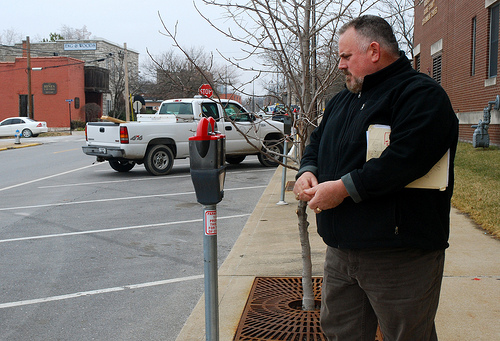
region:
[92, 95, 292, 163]
White pickup truck in parking spot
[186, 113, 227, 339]
Parking meter near street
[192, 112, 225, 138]
Red top of parking meter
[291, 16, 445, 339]
Man in black coat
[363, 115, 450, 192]
Manilla folder under man's arm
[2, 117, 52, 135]
White sedan near brick red building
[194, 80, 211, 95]
Stop sign on street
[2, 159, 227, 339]
White painted lines for parking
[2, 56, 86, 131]
Brick red colored building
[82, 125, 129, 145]
Tailgate of white truck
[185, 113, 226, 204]
a red and black parking meter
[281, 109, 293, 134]
a red and black parking meter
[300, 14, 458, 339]
a man standing on sidewalk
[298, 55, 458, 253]
a black winter coat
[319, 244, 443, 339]
a grey pair of pants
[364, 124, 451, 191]
a manilla file folder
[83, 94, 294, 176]
a parked white pick up truck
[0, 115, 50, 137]
a parked white car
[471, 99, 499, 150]
a grey gas meter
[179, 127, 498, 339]
a paved city sidewalk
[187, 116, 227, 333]
a parking meter on the sidewalk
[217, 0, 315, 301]
a tree with no leaves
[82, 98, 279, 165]
a white pickup truck parked on the street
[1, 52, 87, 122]
a red brick building on the corner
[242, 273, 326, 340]
a metal grate with opening for tree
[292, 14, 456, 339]
a man preparing to put money in parking meter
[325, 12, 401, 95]
a man with a beard and mustache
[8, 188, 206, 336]
white lined parking spaces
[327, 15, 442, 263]
a man holding a folder of papers under arm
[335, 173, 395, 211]
a man wearing black jacket with gray cuffs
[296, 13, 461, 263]
man wearing balck jacket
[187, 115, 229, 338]
silver and red parking meter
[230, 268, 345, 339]
brown grate around tree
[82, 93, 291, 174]
a parked white truck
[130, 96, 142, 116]
back of a stop sign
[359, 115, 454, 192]
vanilla folder under mans arm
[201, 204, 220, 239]
red and white sticker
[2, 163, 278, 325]
white parking lines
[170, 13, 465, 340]
a man getting ready to pay the meter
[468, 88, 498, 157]
a grey electric box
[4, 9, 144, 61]
This is a roof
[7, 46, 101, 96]
This is a roof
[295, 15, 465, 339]
This is a man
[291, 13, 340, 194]
This is a tree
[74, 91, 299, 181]
This is a car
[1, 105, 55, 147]
This is a car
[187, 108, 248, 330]
This is a pole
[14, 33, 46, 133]
This is a pole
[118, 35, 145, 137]
This is a pole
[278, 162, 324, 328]
This is a pole